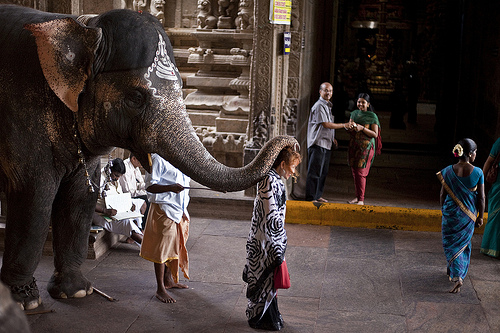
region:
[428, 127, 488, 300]
This is a person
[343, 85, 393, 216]
This is a person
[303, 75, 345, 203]
This is a person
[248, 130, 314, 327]
This is a person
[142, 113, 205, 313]
This is a person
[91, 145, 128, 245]
This is a person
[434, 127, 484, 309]
This is a person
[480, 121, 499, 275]
This is a person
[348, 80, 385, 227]
This is a person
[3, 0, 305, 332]
elephant standing on the street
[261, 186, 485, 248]
yellow paint on the curb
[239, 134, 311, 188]
trunk on the woman's head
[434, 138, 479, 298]
woman wearing a blue sari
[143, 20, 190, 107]
decoration on the elephant's head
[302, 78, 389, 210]
a man and a woman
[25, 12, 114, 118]
spots on the elephants ear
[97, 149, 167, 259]
two men sitting down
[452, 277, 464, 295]
heel is in the air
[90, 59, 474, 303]
people standing near elephant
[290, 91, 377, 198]
people on the curb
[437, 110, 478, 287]
woman is wearing blue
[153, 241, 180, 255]
the pants are orange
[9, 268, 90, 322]
feet of the elephant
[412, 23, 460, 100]
the background is dark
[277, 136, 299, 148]
end of the trunk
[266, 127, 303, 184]
the trunk is on her head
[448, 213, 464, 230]
the dress is blue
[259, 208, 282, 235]
the dress is white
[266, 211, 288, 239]
the flower is black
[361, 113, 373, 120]
the scarf is green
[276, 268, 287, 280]
the bag is red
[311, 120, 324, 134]
the shirt is gray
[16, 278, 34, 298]
the elephant has a chain on its leg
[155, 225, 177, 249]
the skirt is peach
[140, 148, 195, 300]
black pole on the metal fence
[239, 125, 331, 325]
a person standing outside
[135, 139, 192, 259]
a person standing outside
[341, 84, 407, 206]
a person standing outside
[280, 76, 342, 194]
a person standing outside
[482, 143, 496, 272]
a person standing outside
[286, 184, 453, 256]
a yellow line on the sidewalk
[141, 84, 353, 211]
a trunk on the elephant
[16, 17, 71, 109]
an ear on the elephant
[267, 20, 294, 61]
a sign on the wall